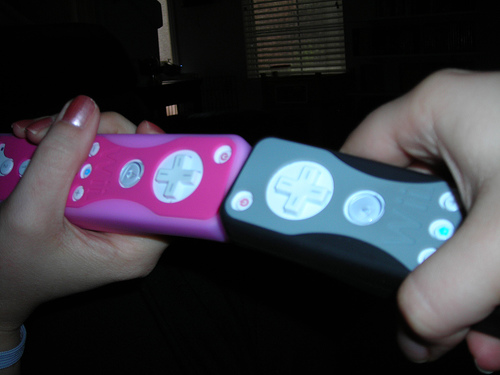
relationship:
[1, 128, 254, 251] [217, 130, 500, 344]
controller touching controller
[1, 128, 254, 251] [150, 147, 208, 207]
controller has function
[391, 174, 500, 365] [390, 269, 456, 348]
thumb has knuckle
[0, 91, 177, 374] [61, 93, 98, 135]
person has fingernail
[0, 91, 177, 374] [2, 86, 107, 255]
person has thumb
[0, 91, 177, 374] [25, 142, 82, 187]
person has knuckle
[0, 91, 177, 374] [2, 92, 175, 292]
person has hand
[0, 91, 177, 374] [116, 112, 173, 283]
person has finger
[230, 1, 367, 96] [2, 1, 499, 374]
window inside of room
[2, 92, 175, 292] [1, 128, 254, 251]
hand holding controller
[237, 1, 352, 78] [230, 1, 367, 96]
blind on top of window